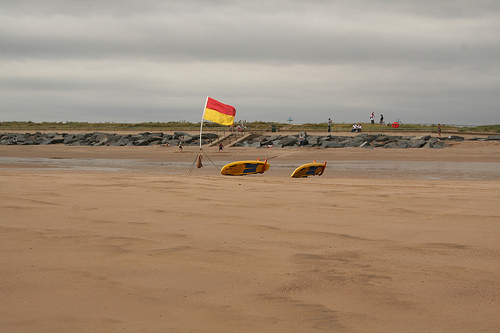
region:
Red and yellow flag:
[195, 90, 242, 131]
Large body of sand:
[79, 198, 249, 308]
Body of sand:
[90, 222, 208, 318]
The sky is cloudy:
[38, 8, 189, 106]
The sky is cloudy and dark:
[296, 20, 411, 97]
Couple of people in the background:
[366, 105, 388, 122]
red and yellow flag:
[185, 86, 252, 131]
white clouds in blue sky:
[20, 5, 52, 36]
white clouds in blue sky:
[365, 49, 409, 91]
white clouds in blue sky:
[430, 103, 472, 117]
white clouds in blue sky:
[372, 32, 427, 60]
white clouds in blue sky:
[314, 33, 339, 57]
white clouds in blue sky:
[178, 12, 223, 57]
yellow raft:
[212, 139, 273, 187]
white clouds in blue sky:
[104, 65, 154, 112]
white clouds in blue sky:
[75, 49, 113, 77]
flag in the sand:
[187, 90, 245, 148]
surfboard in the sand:
[289, 151, 331, 186]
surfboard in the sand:
[213, 153, 281, 178]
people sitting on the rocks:
[291, 128, 315, 143]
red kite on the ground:
[390, 121, 404, 133]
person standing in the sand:
[171, 137, 192, 156]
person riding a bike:
[375, 111, 390, 126]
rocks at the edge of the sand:
[42, 123, 142, 152]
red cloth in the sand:
[385, 116, 403, 131]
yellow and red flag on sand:
[184, 91, 238, 180]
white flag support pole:
[182, 119, 221, 176]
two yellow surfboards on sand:
[216, 155, 333, 182]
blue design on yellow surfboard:
[241, 160, 261, 176]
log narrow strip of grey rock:
[1, 128, 499, 160]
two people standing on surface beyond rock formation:
[363, 104, 386, 125]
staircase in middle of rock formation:
[206, 125, 256, 152]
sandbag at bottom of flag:
[193, 152, 208, 171]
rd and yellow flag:
[199, 89, 240, 131]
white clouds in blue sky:
[344, 46, 380, 82]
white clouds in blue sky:
[277, 36, 297, 68]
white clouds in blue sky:
[191, 24, 217, 61]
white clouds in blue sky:
[20, 16, 49, 35]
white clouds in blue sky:
[89, 34, 139, 81]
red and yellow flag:
[186, 89, 241, 131]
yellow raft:
[224, 153, 276, 198]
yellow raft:
[282, 151, 320, 191]